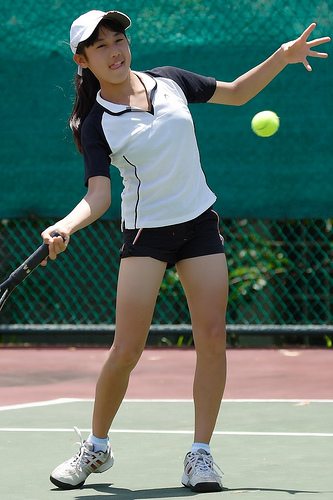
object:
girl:
[40, 9, 331, 492]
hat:
[69, 10, 131, 55]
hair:
[66, 13, 126, 154]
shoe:
[50, 438, 113, 488]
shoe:
[181, 450, 221, 493]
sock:
[87, 432, 109, 452]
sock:
[191, 443, 210, 455]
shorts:
[119, 206, 225, 271]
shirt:
[80, 66, 216, 232]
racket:
[0, 229, 65, 323]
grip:
[9, 230, 64, 288]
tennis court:
[2, 343, 330, 499]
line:
[2, 399, 331, 404]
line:
[1, 428, 332, 436]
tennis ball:
[251, 110, 280, 137]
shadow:
[57, 479, 321, 499]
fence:
[2, 2, 332, 346]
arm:
[150, 46, 281, 106]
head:
[69, 8, 132, 84]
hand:
[39, 225, 70, 266]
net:
[0, 4, 332, 224]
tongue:
[110, 63, 121, 70]